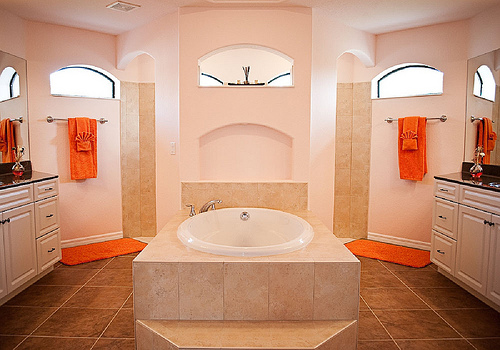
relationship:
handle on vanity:
[441, 186, 472, 199] [432, 170, 480, 275]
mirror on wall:
[465, 50, 497, 113] [438, 44, 478, 140]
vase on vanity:
[459, 140, 492, 192] [432, 170, 480, 275]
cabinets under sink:
[432, 185, 499, 275] [457, 167, 484, 178]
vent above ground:
[110, 2, 140, 15] [64, 235, 131, 348]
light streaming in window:
[211, 51, 290, 89] [373, 66, 464, 104]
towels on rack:
[396, 113, 431, 183] [382, 102, 456, 127]